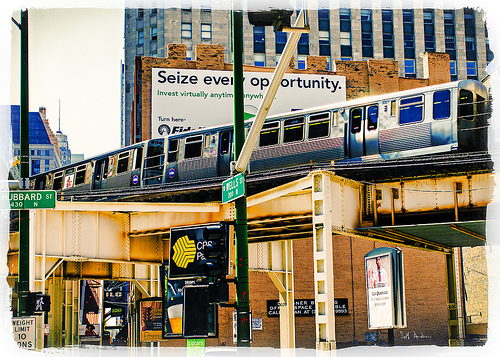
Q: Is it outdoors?
A: Yes, it is outdoors.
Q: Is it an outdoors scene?
A: Yes, it is outdoors.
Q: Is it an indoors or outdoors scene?
A: It is outdoors.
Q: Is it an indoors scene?
A: No, it is outdoors.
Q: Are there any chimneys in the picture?
A: No, there are no chimneys.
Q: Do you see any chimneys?
A: No, there are no chimneys.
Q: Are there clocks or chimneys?
A: No, there are no chimneys or clocks.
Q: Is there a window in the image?
A: Yes, there are windows.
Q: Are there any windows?
A: Yes, there are windows.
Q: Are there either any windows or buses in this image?
A: Yes, there are windows.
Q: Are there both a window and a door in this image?
A: Yes, there are both a window and a door.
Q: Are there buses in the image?
A: No, there are no buses.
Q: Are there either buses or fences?
A: No, there are no buses or fences.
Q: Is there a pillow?
A: No, there are no pillows.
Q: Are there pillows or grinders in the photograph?
A: No, there are no pillows or grinders.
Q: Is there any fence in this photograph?
A: No, there are no fences.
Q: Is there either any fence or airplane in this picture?
A: No, there are no fences or airplanes.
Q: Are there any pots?
A: No, there are no pots.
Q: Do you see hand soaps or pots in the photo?
A: No, there are no pots or hand soaps.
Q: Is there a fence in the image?
A: No, there are no fences.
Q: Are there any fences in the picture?
A: No, there are no fences.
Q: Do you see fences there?
A: No, there are no fences.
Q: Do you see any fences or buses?
A: No, there are no fences or buses.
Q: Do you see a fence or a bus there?
A: No, there are no fences or buses.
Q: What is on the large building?
A: The sign is on the building.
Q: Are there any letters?
A: Yes, there are letters.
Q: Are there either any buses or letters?
A: Yes, there are letters.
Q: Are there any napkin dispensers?
A: No, there are no napkin dispensers.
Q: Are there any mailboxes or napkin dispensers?
A: No, there are no napkin dispensers or mailboxes.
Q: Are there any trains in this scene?
A: Yes, there is a train.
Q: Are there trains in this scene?
A: Yes, there is a train.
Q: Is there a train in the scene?
A: Yes, there is a train.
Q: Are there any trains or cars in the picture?
A: Yes, there is a train.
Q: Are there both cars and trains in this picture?
A: Yes, there are both a train and a car.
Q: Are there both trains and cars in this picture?
A: Yes, there are both a train and a car.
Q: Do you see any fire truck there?
A: No, there are no fire trucks.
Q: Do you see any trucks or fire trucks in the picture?
A: No, there are no fire trucks or trucks.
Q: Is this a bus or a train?
A: This is a train.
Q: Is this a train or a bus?
A: This is a train.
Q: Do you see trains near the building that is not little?
A: Yes, there is a train near the building.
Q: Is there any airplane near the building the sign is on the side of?
A: No, there is a train near the building.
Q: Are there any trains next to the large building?
A: Yes, there is a train next to the building.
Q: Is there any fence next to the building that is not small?
A: No, there is a train next to the building.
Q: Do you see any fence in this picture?
A: No, there are no fences.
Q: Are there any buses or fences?
A: No, there are no fences or buses.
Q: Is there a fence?
A: No, there are no fences.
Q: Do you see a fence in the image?
A: No, there are no fences.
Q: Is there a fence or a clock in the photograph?
A: No, there are no fences or clocks.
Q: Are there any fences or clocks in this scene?
A: No, there are no fences or clocks.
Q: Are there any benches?
A: No, there are no benches.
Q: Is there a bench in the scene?
A: No, there are no benches.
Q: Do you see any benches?
A: No, there are no benches.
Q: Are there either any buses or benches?
A: No, there are no benches or buses.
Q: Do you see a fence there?
A: No, there are no fences.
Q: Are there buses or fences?
A: No, there are no fences or buses.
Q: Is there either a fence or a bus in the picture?
A: No, there are no fences or buses.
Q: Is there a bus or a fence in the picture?
A: No, there are no fences or buses.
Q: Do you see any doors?
A: Yes, there are doors.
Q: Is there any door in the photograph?
A: Yes, there are doors.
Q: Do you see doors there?
A: Yes, there are doors.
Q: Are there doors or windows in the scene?
A: Yes, there are doors.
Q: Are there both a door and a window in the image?
A: Yes, there are both a door and a window.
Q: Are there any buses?
A: No, there are no buses.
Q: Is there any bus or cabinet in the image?
A: No, there are no buses or cabinets.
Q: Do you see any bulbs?
A: No, there are no bulbs.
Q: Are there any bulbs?
A: No, there are no bulbs.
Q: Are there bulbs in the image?
A: No, there are no bulbs.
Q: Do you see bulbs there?
A: No, there are no bulbs.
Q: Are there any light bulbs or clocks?
A: No, there are no light bulbs or clocks.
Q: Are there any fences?
A: No, there are no fences.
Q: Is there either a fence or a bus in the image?
A: No, there are no fences or buses.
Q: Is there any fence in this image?
A: No, there are no fences.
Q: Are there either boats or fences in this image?
A: No, there are no fences or boats.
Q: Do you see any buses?
A: No, there are no buses.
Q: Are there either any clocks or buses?
A: No, there are no buses or clocks.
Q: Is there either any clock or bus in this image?
A: No, there are no buses or clocks.